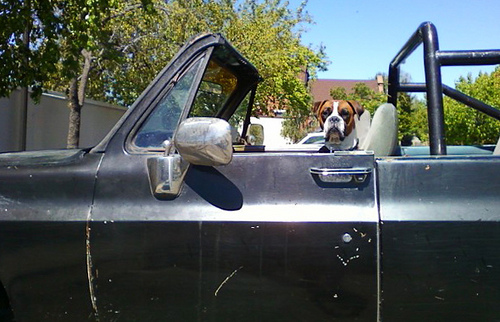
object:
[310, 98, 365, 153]
dog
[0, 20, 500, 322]
car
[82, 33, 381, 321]
door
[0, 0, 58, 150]
tree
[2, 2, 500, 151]
background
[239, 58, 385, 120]
building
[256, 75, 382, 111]
roof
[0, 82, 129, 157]
wall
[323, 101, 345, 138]
stripe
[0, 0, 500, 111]
sky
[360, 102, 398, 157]
seats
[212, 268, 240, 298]
scratches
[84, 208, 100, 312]
rust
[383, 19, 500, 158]
roll bars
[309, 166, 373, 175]
handle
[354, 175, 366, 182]
key slot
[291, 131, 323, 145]
another car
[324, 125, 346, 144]
jowls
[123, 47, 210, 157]
window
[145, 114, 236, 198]
mirror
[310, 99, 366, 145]
face